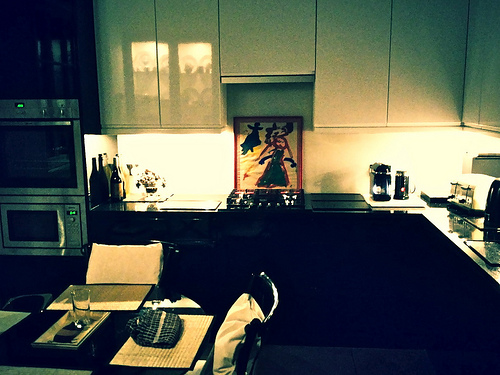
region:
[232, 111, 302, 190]
the picture on the wall behind the counter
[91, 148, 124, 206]
the bottles on the counter top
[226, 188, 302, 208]
the stovetop on the counter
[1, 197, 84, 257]
the microwave beneath the oven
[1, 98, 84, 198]
the oven on the wall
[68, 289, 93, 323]
the cup on the table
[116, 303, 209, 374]
the table cloth on the dinner table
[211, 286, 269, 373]
the cushion on the chair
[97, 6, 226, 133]
the cupboard above the counter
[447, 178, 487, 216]
the toaster on the top of the counter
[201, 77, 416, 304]
the photo is on the wall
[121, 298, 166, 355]
a towel is on the napkin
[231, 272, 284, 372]
a pillow is in the chair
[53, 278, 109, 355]
a glass in on the table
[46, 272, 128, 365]
a glass is in a bowl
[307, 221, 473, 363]
the cabinets are dark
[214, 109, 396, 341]
the photo is over the stove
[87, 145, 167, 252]
bottles are on the counter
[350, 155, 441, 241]
coffee pots are on the counter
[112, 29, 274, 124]
the cabinets are white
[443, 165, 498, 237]
silver and black four slot toaster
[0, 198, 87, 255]
shiny silver microwave oven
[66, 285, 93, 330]
empty transparent glass on table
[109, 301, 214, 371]
rectangular bamboo place mat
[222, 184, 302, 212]
wrought iron cook top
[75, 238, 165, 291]
square white pillow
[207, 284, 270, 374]
square white pillow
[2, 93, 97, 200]
stainless steel elevated oven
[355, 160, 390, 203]
one cup coffee machin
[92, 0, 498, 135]
shiny reflective white cabinetry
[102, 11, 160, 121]
cabinets are painted with shiny paint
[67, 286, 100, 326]
empty glass sitting on table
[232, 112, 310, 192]
colorful art on wall behind stove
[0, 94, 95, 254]
appliances are stainless steel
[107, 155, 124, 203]
wine bottles on the counter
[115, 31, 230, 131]
reflection of window in cabinet doors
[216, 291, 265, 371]
white pillow sitting on chair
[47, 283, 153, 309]
tan colored placemat on table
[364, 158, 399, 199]
coffee pot on the counter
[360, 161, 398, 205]
black coffee pot on the counter